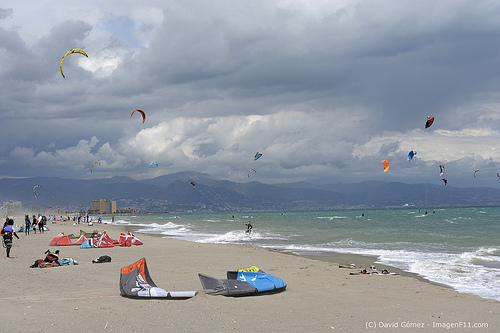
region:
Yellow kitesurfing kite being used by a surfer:
[56, 40, 93, 77]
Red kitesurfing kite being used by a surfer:
[127, 107, 148, 124]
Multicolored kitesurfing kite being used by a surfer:
[251, 148, 266, 162]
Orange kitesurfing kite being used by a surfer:
[379, 158, 390, 171]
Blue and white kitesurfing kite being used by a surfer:
[405, 148, 419, 164]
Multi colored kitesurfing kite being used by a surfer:
[424, 113, 436, 130]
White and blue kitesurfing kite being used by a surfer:
[436, 162, 446, 177]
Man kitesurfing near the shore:
[242, 218, 257, 235]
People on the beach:
[0, 210, 124, 268]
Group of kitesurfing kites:
[363, 109, 498, 191]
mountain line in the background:
[0, 160, 498, 208]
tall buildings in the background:
[0, 193, 120, 215]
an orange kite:
[378, 155, 392, 173]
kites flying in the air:
[16, 27, 499, 189]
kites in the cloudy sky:
[10, 32, 499, 187]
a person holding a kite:
[2, 216, 21, 258]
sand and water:
[299, 230, 496, 302]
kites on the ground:
[108, 251, 293, 308]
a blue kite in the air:
[404, 148, 419, 161]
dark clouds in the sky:
[155, 14, 496, 109]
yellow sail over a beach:
[56, 45, 91, 78]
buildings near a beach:
[0, 197, 129, 217]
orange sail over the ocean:
[379, 156, 391, 174]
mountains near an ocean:
[2, 173, 498, 210]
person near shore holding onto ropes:
[243, 219, 254, 235]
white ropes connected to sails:
[67, 58, 246, 229]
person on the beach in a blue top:
[3, 223, 15, 233]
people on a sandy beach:
[1, 205, 119, 263]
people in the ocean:
[224, 208, 435, 232]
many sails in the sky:
[29, 43, 499, 198]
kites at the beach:
[50, 44, 496, 234]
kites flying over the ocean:
[45, 43, 498, 240]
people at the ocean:
[2, 196, 114, 264]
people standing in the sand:
[2, 201, 99, 258]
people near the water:
[45, 201, 146, 236]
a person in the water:
[242, 213, 263, 239]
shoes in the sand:
[336, 255, 395, 282]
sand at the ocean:
[322, 290, 473, 332]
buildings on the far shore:
[87, 190, 124, 219]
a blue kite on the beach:
[200, 266, 285, 297]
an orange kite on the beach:
[117, 261, 191, 299]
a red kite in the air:
[425, 116, 432, 127]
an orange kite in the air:
[380, 158, 389, 172]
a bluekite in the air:
[405, 148, 417, 162]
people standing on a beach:
[4, 211, 46, 261]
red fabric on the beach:
[50, 230, 143, 248]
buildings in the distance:
[86, 199, 118, 212]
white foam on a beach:
[375, 245, 497, 298]